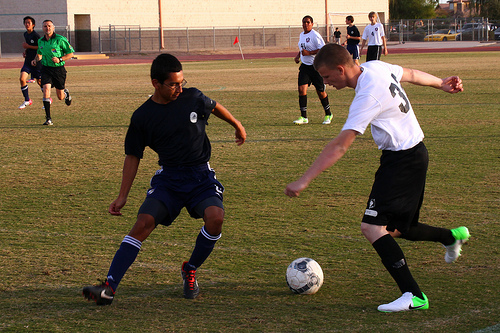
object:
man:
[289, 39, 473, 313]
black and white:
[338, 59, 433, 229]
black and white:
[292, 28, 327, 92]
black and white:
[363, 22, 387, 62]